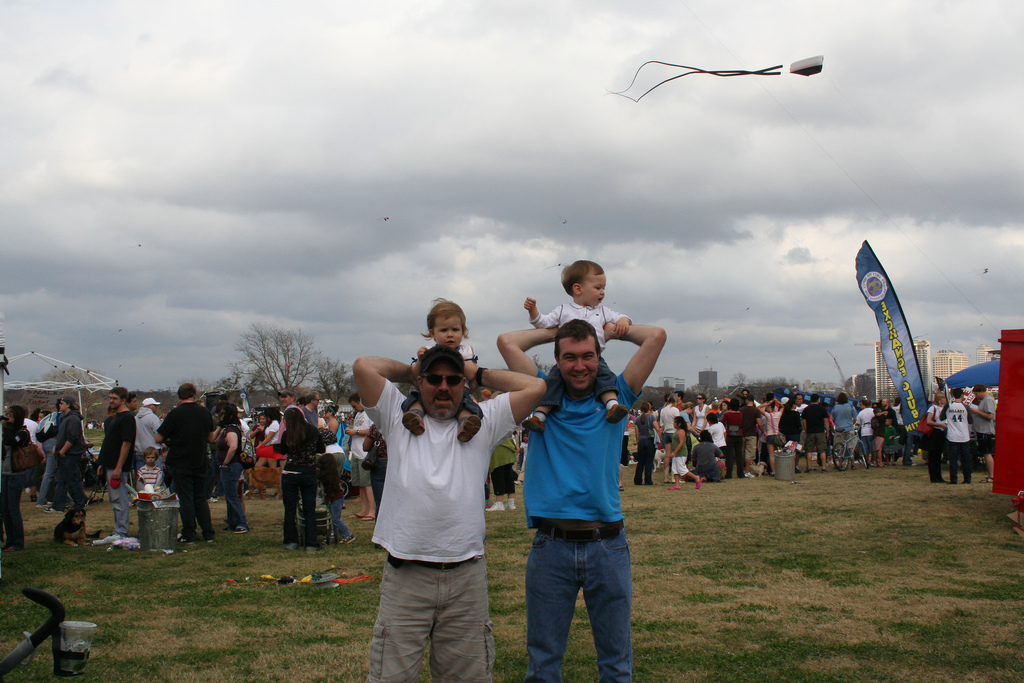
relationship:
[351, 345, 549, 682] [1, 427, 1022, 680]
man on field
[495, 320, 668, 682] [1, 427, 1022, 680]
man on field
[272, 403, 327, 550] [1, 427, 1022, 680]
person on field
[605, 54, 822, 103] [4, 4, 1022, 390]
kite in sky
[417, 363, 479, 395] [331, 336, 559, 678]
glasses of a man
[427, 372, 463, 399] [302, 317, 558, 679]
nose of a man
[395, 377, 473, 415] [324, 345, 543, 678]
mouth of a man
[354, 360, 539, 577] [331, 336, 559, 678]
shirt of a man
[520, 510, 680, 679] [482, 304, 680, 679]
jeans of a man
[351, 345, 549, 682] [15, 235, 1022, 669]
man of standing at festival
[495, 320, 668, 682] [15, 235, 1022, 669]
man standing at festival